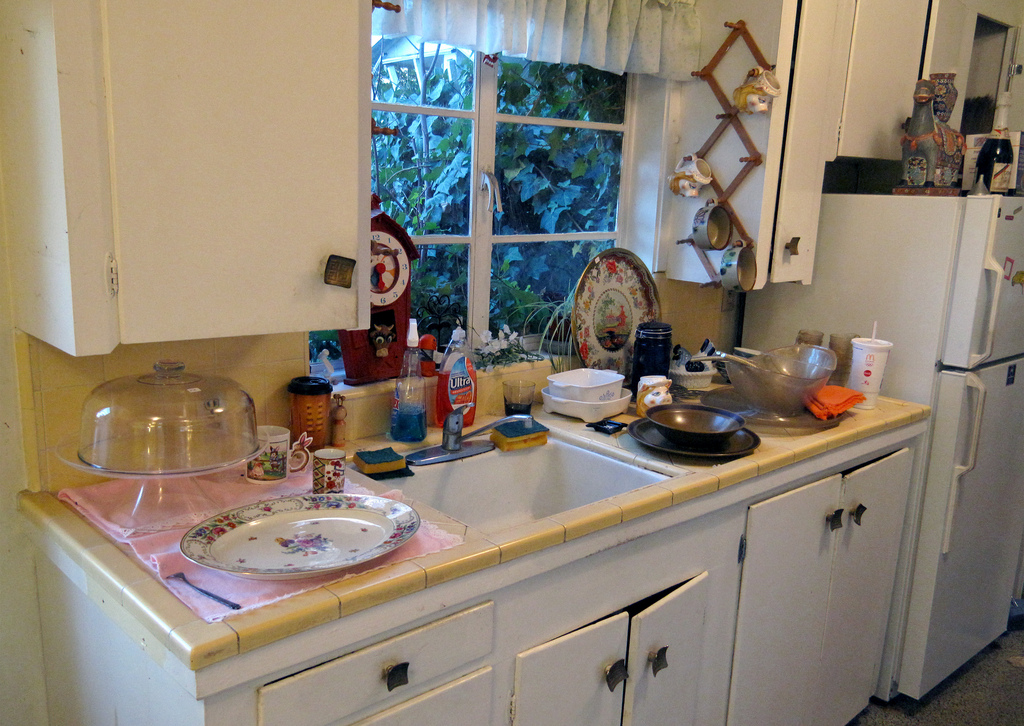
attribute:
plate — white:
[182, 492, 426, 578]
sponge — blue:
[354, 444, 406, 476]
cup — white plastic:
[849, 323, 891, 400]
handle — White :
[960, 373, 984, 475]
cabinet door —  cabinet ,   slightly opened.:
[511, 604, 626, 723]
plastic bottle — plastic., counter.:
[393, 317, 435, 439]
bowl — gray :
[647, 405, 745, 453]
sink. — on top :
[360, 433, 657, 522]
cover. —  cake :
[52, 355, 286, 544]